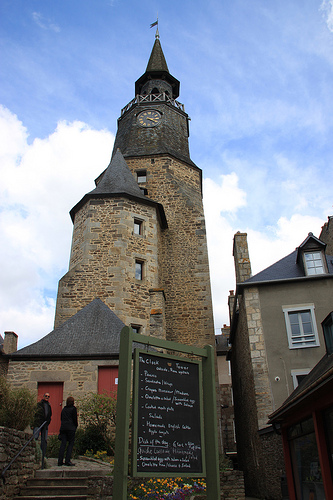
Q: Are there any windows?
A: Yes, there is a window.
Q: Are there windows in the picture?
A: Yes, there is a window.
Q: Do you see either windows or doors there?
A: Yes, there is a window.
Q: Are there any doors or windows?
A: Yes, there is a window.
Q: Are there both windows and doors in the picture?
A: Yes, there are both a window and a door.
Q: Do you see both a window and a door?
A: Yes, there are both a window and a door.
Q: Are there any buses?
A: No, there are no buses.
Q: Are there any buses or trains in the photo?
A: No, there are no buses or trains.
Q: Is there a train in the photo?
A: No, there are no trains.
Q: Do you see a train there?
A: No, there are no trains.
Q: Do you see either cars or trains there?
A: No, there are no trains or cars.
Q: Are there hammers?
A: No, there are no hammers.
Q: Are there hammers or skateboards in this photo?
A: No, there are no hammers or skateboards.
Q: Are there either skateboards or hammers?
A: No, there are no hammers or skateboards.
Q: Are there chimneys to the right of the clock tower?
A: Yes, there is a chimney to the right of the clock tower.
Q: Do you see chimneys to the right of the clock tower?
A: Yes, there is a chimney to the right of the clock tower.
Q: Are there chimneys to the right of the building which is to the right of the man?
A: Yes, there is a chimney to the right of the clock tower.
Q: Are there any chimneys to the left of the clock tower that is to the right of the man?
A: No, the chimney is to the right of the clock tower.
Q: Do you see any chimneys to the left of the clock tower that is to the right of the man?
A: No, the chimney is to the right of the clock tower.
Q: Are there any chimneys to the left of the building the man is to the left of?
A: No, the chimney is to the right of the clock tower.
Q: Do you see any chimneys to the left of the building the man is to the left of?
A: No, the chimney is to the right of the clock tower.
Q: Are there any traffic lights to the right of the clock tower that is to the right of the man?
A: No, there is a chimney to the right of the clock tower.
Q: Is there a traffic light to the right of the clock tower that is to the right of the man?
A: No, there is a chimney to the right of the clock tower.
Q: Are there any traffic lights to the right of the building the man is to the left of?
A: No, there is a chimney to the right of the clock tower.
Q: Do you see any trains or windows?
A: Yes, there is a window.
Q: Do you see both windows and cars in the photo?
A: No, there is a window but no cars.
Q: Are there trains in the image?
A: No, there are no trains.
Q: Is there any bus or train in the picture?
A: No, there are no trains or buses.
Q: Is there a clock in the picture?
A: Yes, there is a clock.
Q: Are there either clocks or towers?
A: Yes, there is a clock.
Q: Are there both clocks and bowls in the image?
A: No, there is a clock but no bowls.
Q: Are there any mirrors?
A: No, there are no mirrors.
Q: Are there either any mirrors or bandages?
A: No, there are no mirrors or bandages.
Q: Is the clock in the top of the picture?
A: Yes, the clock is in the top of the image.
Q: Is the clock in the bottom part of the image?
A: No, the clock is in the top of the image.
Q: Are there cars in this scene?
A: No, there are no cars.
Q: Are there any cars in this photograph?
A: No, there are no cars.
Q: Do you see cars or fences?
A: No, there are no cars or fences.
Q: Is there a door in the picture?
A: Yes, there is a door.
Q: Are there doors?
A: Yes, there is a door.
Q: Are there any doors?
A: Yes, there is a door.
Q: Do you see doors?
A: Yes, there is a door.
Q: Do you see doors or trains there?
A: Yes, there is a door.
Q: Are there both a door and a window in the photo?
A: Yes, there are both a door and a window.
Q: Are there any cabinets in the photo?
A: No, there are no cabinets.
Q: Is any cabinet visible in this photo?
A: No, there are no cabinets.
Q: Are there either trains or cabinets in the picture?
A: No, there are no cabinets or trains.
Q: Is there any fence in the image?
A: No, there are no fences.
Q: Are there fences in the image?
A: No, there are no fences.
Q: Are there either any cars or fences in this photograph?
A: No, there are no fences or cars.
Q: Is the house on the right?
A: Yes, the house is on the right of the image.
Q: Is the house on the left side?
A: No, the house is on the right of the image.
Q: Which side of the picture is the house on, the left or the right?
A: The house is on the right of the image.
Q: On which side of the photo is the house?
A: The house is on the right of the image.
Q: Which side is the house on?
A: The house is on the right of the image.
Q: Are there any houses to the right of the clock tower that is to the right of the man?
A: Yes, there is a house to the right of the clock tower.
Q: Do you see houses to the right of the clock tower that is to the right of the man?
A: Yes, there is a house to the right of the clock tower.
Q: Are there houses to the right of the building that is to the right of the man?
A: Yes, there is a house to the right of the clock tower.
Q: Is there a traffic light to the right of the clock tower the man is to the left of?
A: No, there is a house to the right of the clock tower.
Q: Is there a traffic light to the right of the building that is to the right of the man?
A: No, there is a house to the right of the clock tower.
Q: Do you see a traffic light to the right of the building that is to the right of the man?
A: No, there is a house to the right of the clock tower.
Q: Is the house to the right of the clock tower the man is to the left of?
A: Yes, the house is to the right of the clock tower.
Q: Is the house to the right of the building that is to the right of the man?
A: Yes, the house is to the right of the clock tower.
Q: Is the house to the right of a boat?
A: No, the house is to the right of the clock tower.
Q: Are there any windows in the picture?
A: Yes, there is a window.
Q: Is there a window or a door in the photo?
A: Yes, there is a window.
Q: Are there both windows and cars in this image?
A: No, there is a window but no cars.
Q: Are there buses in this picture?
A: No, there are no buses.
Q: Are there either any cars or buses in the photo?
A: No, there are no buses or cars.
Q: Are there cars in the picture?
A: No, there are no cars.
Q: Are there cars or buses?
A: No, there are no cars or buses.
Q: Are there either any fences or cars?
A: No, there are no cars or fences.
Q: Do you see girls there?
A: No, there are no girls.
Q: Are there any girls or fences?
A: No, there are no girls or fences.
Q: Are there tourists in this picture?
A: No, there are no tourists.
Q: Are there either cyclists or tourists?
A: No, there are no tourists or cyclists.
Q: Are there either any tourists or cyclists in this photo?
A: No, there are no tourists or cyclists.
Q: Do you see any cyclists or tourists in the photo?
A: No, there are no tourists or cyclists.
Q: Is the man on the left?
A: Yes, the man is on the left of the image.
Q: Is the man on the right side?
A: No, the man is on the left of the image.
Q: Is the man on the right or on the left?
A: The man is on the left of the image.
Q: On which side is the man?
A: The man is on the left of the image.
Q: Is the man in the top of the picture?
A: No, the man is in the bottom of the image.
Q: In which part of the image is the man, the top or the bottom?
A: The man is in the bottom of the image.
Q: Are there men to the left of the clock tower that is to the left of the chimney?
A: Yes, there is a man to the left of the clock tower.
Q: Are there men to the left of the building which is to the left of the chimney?
A: Yes, there is a man to the left of the clock tower.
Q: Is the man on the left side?
A: Yes, the man is on the left of the image.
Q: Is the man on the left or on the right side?
A: The man is on the left of the image.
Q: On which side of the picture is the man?
A: The man is on the left of the image.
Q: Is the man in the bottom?
A: Yes, the man is in the bottom of the image.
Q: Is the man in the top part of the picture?
A: No, the man is in the bottom of the image.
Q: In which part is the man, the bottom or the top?
A: The man is in the bottom of the image.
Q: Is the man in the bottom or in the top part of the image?
A: The man is in the bottom of the image.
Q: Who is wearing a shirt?
A: The man is wearing a shirt.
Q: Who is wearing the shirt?
A: The man is wearing a shirt.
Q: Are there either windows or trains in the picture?
A: Yes, there is a window.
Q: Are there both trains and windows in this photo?
A: No, there is a window but no trains.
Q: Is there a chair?
A: No, there are no chairs.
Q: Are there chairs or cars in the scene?
A: No, there are no chairs or cars.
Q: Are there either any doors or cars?
A: Yes, there is a door.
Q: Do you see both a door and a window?
A: Yes, there are both a door and a window.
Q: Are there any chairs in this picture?
A: No, there are no chairs.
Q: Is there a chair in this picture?
A: No, there are no chairs.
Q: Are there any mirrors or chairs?
A: No, there are no chairs or mirrors.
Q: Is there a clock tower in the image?
A: Yes, there is a clock tower.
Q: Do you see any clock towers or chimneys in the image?
A: Yes, there is a clock tower.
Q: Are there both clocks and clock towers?
A: Yes, there are both a clock tower and a clock.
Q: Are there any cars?
A: No, there are no cars.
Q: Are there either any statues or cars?
A: No, there are no cars or statues.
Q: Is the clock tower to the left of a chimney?
A: Yes, the clock tower is to the left of a chimney.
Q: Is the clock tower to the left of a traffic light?
A: No, the clock tower is to the left of a chimney.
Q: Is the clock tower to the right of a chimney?
A: No, the clock tower is to the left of a chimney.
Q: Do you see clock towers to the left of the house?
A: Yes, there is a clock tower to the left of the house.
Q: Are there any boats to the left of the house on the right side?
A: No, there is a clock tower to the left of the house.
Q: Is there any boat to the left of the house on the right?
A: No, there is a clock tower to the left of the house.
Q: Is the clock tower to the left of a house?
A: Yes, the clock tower is to the left of a house.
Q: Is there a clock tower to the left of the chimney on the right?
A: Yes, there is a clock tower to the left of the chimney.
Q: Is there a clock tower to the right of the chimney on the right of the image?
A: No, the clock tower is to the left of the chimney.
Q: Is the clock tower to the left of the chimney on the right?
A: Yes, the clock tower is to the left of the chimney.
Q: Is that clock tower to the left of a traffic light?
A: No, the clock tower is to the left of the chimney.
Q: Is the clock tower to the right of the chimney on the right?
A: No, the clock tower is to the left of the chimney.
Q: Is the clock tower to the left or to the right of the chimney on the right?
A: The clock tower is to the left of the chimney.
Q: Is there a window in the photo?
A: Yes, there is a window.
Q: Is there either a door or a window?
A: Yes, there is a window.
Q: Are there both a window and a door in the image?
A: Yes, there are both a window and a door.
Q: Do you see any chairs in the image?
A: No, there are no chairs.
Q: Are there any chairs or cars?
A: No, there are no chairs or cars.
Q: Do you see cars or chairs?
A: No, there are no chairs or cars.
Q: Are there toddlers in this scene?
A: No, there are no toddlers.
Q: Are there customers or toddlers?
A: No, there are no toddlers or customers.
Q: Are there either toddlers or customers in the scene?
A: No, there are no toddlers or customers.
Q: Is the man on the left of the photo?
A: Yes, the man is on the left of the image.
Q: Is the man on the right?
A: No, the man is on the left of the image.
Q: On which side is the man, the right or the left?
A: The man is on the left of the image.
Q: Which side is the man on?
A: The man is on the left of the image.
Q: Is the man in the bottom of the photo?
A: Yes, the man is in the bottom of the image.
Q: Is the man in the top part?
A: No, the man is in the bottom of the image.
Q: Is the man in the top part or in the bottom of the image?
A: The man is in the bottom of the image.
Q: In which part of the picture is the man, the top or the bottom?
A: The man is in the bottom of the image.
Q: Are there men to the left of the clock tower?
A: Yes, there is a man to the left of the clock tower.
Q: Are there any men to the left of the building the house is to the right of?
A: Yes, there is a man to the left of the clock tower.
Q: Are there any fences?
A: No, there are no fences.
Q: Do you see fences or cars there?
A: No, there are no fences or cars.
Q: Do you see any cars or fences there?
A: No, there are no fences or cars.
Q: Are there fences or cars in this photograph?
A: No, there are no fences or cars.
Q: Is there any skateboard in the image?
A: No, there are no skateboards.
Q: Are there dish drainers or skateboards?
A: No, there are no skateboards or dish drainers.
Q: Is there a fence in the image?
A: No, there are no fences.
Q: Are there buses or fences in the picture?
A: No, there are no fences or buses.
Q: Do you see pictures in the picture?
A: No, there are no pictures.